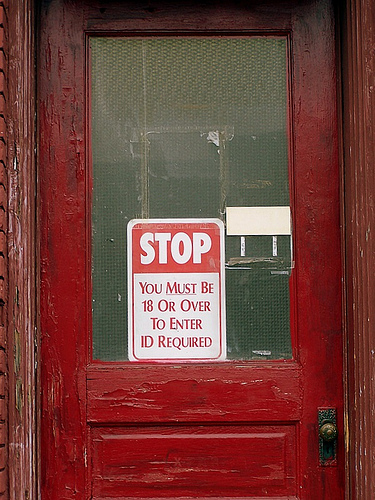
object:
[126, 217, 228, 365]
sign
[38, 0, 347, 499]
door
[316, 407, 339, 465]
door knob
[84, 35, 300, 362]
pane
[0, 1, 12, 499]
wall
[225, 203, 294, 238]
paper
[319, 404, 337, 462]
plate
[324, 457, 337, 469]
paint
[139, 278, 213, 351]
lettering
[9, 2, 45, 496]
door frame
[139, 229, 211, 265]
stop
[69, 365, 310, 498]
panels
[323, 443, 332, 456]
key hole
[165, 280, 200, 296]
word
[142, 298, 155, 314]
number